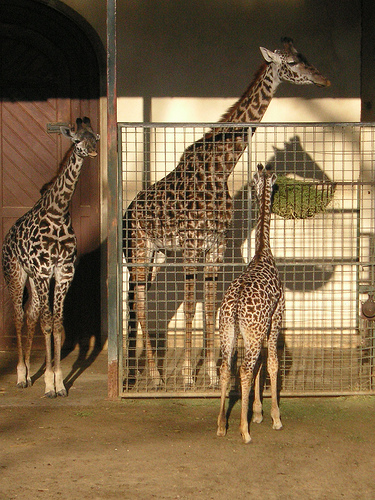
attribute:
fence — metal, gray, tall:
[126, 125, 222, 398]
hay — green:
[279, 172, 319, 204]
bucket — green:
[271, 176, 338, 219]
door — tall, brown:
[6, 6, 102, 133]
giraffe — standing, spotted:
[5, 116, 107, 403]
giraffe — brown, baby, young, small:
[207, 165, 302, 446]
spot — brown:
[42, 242, 56, 253]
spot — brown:
[43, 202, 64, 221]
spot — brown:
[261, 85, 278, 103]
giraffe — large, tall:
[93, 35, 333, 378]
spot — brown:
[211, 154, 222, 176]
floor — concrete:
[74, 356, 108, 410]